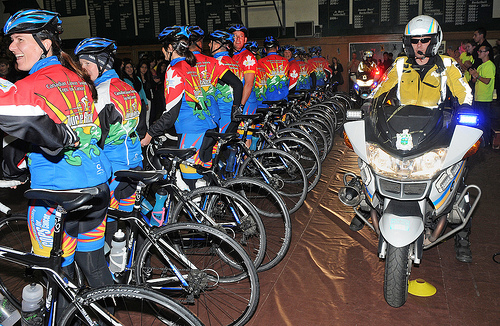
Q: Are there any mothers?
A: No, there are no mothers.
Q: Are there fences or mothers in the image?
A: No, there are no mothers or fences.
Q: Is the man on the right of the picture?
A: Yes, the man is on the right of the image.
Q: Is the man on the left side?
A: No, the man is on the right of the image.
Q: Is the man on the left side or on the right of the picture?
A: The man is on the right of the image.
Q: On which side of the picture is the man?
A: The man is on the right of the image.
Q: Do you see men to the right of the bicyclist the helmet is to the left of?
A: Yes, there is a man to the right of the bicyclist.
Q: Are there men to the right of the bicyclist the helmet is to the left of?
A: Yes, there is a man to the right of the bicyclist.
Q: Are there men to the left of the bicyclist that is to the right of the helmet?
A: No, the man is to the right of the bicyclist.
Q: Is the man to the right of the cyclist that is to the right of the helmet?
A: Yes, the man is to the right of the bicyclist.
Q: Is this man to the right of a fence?
A: No, the man is to the right of the bicyclist.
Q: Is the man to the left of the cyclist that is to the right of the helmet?
A: No, the man is to the right of the bicyclist.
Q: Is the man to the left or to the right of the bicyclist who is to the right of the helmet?
A: The man is to the right of the cyclist.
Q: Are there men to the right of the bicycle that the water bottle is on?
A: Yes, there is a man to the right of the bicycle.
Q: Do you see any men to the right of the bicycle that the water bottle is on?
A: Yes, there is a man to the right of the bicycle.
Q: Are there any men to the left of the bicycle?
A: No, the man is to the right of the bicycle.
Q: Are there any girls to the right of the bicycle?
A: No, there is a man to the right of the bicycle.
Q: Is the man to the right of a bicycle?
A: Yes, the man is to the right of a bicycle.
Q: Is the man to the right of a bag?
A: No, the man is to the right of a bicycle.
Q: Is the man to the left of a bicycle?
A: No, the man is to the right of a bicycle.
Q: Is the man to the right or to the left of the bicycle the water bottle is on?
A: The man is to the right of the bicycle.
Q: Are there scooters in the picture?
A: No, there are no scooters.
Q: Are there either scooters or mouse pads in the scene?
A: No, there are no scooters or mouse pads.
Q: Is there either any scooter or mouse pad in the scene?
A: No, there are no scooters or mouse pads.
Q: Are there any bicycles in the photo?
A: Yes, there is a bicycle.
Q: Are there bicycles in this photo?
A: Yes, there is a bicycle.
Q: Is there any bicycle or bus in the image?
A: Yes, there is a bicycle.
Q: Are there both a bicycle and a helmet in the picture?
A: Yes, there are both a bicycle and a helmet.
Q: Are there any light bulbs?
A: No, there are no light bulbs.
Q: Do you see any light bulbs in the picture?
A: No, there are no light bulbs.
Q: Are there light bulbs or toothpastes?
A: No, there are no light bulbs or toothpastes.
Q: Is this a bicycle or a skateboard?
A: This is a bicycle.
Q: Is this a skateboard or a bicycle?
A: This is a bicycle.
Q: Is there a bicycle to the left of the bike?
A: Yes, there is a bicycle to the left of the bike.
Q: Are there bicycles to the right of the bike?
A: No, the bicycle is to the left of the bike.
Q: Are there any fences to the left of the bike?
A: No, there is a bicycle to the left of the bike.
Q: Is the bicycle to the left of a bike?
A: Yes, the bicycle is to the left of a bike.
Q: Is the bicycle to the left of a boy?
A: No, the bicycle is to the left of a bike.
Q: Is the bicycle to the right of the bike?
A: No, the bicycle is to the left of the bike.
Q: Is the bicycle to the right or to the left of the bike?
A: The bicycle is to the left of the bike.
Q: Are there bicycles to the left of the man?
A: Yes, there is a bicycle to the left of the man.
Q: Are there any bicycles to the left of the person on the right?
A: Yes, there is a bicycle to the left of the man.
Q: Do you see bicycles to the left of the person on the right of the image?
A: Yes, there is a bicycle to the left of the man.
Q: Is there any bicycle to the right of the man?
A: No, the bicycle is to the left of the man.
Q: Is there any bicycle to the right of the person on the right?
A: No, the bicycle is to the left of the man.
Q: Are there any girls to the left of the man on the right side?
A: No, there is a bicycle to the left of the man.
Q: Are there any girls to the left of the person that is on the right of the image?
A: No, there is a bicycle to the left of the man.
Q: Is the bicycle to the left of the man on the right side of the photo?
A: Yes, the bicycle is to the left of the man.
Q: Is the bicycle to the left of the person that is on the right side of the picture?
A: Yes, the bicycle is to the left of the man.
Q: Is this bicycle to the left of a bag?
A: No, the bicycle is to the left of the man.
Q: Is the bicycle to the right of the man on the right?
A: No, the bicycle is to the left of the man.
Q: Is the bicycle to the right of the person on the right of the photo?
A: No, the bicycle is to the left of the man.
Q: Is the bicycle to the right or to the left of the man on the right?
A: The bicycle is to the left of the man.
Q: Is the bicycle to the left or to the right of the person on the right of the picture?
A: The bicycle is to the left of the man.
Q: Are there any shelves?
A: No, there are no shelves.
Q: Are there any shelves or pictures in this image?
A: No, there are no shelves or pictures.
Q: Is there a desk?
A: No, there are no desks.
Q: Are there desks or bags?
A: No, there are no desks or bags.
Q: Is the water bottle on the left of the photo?
A: Yes, the water bottle is on the left of the image.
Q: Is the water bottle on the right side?
A: No, the water bottle is on the left of the image.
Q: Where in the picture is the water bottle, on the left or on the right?
A: The water bottle is on the left of the image.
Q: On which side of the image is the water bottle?
A: The water bottle is on the left of the image.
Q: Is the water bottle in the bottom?
A: Yes, the water bottle is in the bottom of the image.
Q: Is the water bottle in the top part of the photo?
A: No, the water bottle is in the bottom of the image.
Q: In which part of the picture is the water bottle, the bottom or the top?
A: The water bottle is in the bottom of the image.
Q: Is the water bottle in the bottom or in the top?
A: The water bottle is in the bottom of the image.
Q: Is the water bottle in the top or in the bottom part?
A: The water bottle is in the bottom of the image.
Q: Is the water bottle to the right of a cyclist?
A: Yes, the water bottle is to the right of a cyclist.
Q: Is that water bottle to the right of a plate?
A: No, the water bottle is to the right of a cyclist.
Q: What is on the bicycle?
A: The water bottle is on the bicycle.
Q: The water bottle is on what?
A: The water bottle is on the bicycle.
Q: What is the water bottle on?
A: The water bottle is on the bicycle.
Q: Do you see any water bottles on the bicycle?
A: Yes, there is a water bottle on the bicycle.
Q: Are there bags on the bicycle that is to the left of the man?
A: No, there is a water bottle on the bicycle.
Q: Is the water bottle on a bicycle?
A: Yes, the water bottle is on a bicycle.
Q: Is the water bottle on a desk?
A: No, the water bottle is on a bicycle.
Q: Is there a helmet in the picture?
A: Yes, there is a helmet.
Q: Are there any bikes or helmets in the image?
A: Yes, there is a helmet.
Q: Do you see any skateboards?
A: No, there are no skateboards.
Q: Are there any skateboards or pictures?
A: No, there are no skateboards or pictures.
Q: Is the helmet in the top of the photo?
A: Yes, the helmet is in the top of the image.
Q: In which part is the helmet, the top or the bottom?
A: The helmet is in the top of the image.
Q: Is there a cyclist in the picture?
A: Yes, there is a cyclist.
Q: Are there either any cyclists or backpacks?
A: Yes, there is a cyclist.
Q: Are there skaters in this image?
A: No, there are no skaters.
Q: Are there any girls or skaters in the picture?
A: No, there are no skaters or girls.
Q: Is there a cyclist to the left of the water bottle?
A: Yes, there is a cyclist to the left of the water bottle.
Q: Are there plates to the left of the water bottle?
A: No, there is a cyclist to the left of the water bottle.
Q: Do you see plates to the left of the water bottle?
A: No, there is a cyclist to the left of the water bottle.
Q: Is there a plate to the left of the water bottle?
A: No, there is a cyclist to the left of the water bottle.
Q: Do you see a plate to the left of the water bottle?
A: No, there is a cyclist to the left of the water bottle.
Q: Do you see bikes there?
A: Yes, there is a bike.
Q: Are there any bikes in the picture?
A: Yes, there is a bike.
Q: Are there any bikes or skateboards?
A: Yes, there is a bike.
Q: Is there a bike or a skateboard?
A: Yes, there is a bike.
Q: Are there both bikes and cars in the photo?
A: No, there is a bike but no cars.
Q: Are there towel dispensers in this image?
A: No, there are no towel dispensers.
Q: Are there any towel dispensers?
A: No, there are no towel dispensers.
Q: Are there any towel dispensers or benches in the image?
A: No, there are no towel dispensers or benches.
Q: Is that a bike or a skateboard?
A: That is a bike.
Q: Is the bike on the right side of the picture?
A: Yes, the bike is on the right of the image.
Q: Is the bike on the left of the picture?
A: No, the bike is on the right of the image.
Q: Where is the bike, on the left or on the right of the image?
A: The bike is on the right of the image.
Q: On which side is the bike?
A: The bike is on the right of the image.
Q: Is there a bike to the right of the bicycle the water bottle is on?
A: Yes, there is a bike to the right of the bicycle.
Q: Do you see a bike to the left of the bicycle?
A: No, the bike is to the right of the bicycle.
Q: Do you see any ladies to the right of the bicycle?
A: No, there is a bike to the right of the bicycle.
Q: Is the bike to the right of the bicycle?
A: Yes, the bike is to the right of the bicycle.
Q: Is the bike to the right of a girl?
A: No, the bike is to the right of the bicycle.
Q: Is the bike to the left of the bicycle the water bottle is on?
A: No, the bike is to the right of the bicycle.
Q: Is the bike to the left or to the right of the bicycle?
A: The bike is to the right of the bicycle.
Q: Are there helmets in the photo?
A: Yes, there is a helmet.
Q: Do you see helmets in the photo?
A: Yes, there is a helmet.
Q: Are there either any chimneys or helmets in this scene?
A: Yes, there is a helmet.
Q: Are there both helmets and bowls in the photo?
A: No, there is a helmet but no bowls.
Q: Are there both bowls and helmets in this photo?
A: No, there is a helmet but no bowls.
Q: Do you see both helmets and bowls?
A: No, there is a helmet but no bowls.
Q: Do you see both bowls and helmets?
A: No, there is a helmet but no bowls.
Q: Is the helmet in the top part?
A: Yes, the helmet is in the top of the image.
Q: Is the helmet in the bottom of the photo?
A: No, the helmet is in the top of the image.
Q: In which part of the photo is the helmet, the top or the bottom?
A: The helmet is in the top of the image.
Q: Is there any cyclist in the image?
A: Yes, there is a cyclist.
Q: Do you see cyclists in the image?
A: Yes, there is a cyclist.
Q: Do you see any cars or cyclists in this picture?
A: Yes, there is a cyclist.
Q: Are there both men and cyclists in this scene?
A: Yes, there are both a cyclist and a man.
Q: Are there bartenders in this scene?
A: No, there are no bartenders.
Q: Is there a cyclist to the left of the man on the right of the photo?
A: Yes, there is a cyclist to the left of the man.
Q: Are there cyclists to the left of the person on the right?
A: Yes, there is a cyclist to the left of the man.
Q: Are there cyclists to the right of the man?
A: No, the cyclist is to the left of the man.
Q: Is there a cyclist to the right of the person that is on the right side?
A: No, the cyclist is to the left of the man.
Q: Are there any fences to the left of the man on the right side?
A: No, there is a cyclist to the left of the man.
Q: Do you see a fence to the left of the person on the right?
A: No, there is a cyclist to the left of the man.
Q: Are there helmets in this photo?
A: Yes, there is a helmet.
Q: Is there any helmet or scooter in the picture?
A: Yes, there is a helmet.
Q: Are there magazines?
A: No, there are no magazines.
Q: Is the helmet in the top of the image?
A: Yes, the helmet is in the top of the image.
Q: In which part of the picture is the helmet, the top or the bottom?
A: The helmet is in the top of the image.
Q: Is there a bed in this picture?
A: No, there are no beds.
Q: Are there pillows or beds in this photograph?
A: No, there are no beds or pillows.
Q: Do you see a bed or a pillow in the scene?
A: No, there are no beds or pillows.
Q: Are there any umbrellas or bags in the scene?
A: No, there are no bags or umbrellas.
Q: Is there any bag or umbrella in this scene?
A: No, there are no bags or umbrellas.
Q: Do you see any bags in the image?
A: No, there are no bags.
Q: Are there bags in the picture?
A: No, there are no bags.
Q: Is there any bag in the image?
A: No, there are no bags.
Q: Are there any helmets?
A: Yes, there is a helmet.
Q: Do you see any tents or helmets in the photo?
A: Yes, there is a helmet.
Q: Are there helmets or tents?
A: Yes, there is a helmet.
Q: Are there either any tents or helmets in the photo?
A: Yes, there is a helmet.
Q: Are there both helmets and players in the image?
A: No, there is a helmet but no players.